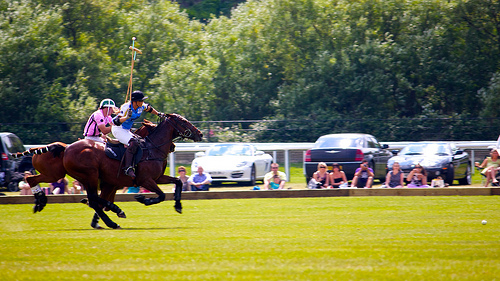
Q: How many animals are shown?
A: Two.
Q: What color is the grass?
A: Green.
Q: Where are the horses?
A: On grass.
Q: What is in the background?
A: Trees.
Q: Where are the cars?
A: Parking lot.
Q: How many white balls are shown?
A: One.